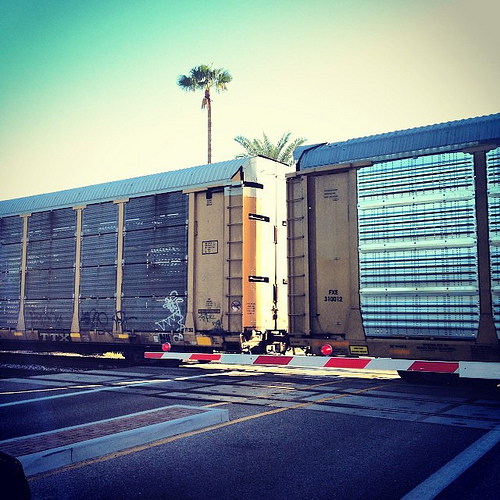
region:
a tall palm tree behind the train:
[172, 47, 227, 153]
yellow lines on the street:
[235, 385, 315, 412]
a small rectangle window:
[250, 205, 271, 221]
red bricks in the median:
[30, 435, 66, 450]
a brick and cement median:
[50, 390, 230, 450]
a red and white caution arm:
[150, 345, 495, 375]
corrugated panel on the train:
[31, 213, 83, 332]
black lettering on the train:
[325, 284, 345, 309]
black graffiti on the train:
[76, 303, 127, 330]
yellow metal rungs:
[284, 172, 312, 329]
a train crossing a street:
[6, 60, 498, 429]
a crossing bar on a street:
[128, 323, 499, 387]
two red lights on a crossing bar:
[150, 332, 348, 359]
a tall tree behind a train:
[176, 59, 236, 169]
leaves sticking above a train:
[230, 124, 312, 165]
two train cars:
[0, 151, 497, 368]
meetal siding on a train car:
[345, 158, 487, 348]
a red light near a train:
[318, 339, 337, 359]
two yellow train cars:
[16, 91, 491, 377]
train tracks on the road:
[63, 360, 499, 435]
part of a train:
[398, 328, 413, 348]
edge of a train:
[193, 293, 198, 306]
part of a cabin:
[191, 148, 228, 276]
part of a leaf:
[261, 129, 280, 144]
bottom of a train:
[175, 350, 182, 364]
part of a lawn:
[176, 428, 177, 431]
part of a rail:
[186, 315, 209, 358]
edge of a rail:
[182, 362, 217, 412]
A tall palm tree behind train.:
[186, 40, 311, 167]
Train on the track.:
[40, 189, 449, 335]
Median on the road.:
[37, 396, 237, 448]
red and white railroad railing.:
[132, 333, 442, 388]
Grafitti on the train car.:
[71, 285, 201, 340]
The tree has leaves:
[179, 57, 242, 93]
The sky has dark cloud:
[11, 20, 207, 72]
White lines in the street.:
[400, 429, 485, 498]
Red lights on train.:
[311, 329, 346, 358]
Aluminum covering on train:
[301, 131, 447, 161]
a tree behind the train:
[175, 61, 236, 148]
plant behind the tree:
[235, 130, 310, 161]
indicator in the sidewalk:
[316, 340, 332, 356]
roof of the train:
[71, 161, 241, 196]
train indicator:
[319, 343, 334, 361]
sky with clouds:
[278, 13, 460, 100]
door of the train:
[192, 192, 235, 336]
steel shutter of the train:
[366, 173, 481, 333]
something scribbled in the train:
[152, 288, 191, 333]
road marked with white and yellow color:
[36, 368, 311, 498]